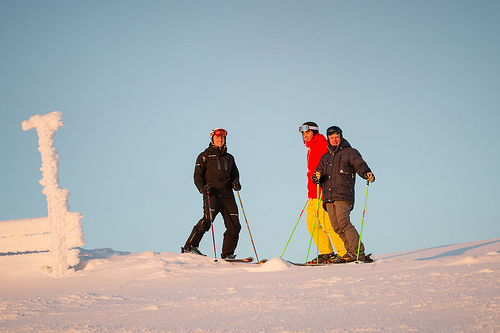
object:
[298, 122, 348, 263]
skier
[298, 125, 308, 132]
goggles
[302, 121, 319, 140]
head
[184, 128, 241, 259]
skier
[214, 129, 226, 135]
goggles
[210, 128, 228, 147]
head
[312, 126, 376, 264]
skier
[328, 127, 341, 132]
goggles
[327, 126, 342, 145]
head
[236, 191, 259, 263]
pole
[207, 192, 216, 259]
pole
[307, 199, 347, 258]
pants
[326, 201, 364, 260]
pants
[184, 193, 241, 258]
pants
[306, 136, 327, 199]
coat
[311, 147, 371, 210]
coat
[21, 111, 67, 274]
sculputure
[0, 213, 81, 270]
ice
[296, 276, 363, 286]
tracks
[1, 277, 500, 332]
snow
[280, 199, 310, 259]
poles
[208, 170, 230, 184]
black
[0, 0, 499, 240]
sky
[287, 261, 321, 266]
skies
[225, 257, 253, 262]
skies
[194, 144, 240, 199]
jacket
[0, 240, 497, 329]
ground